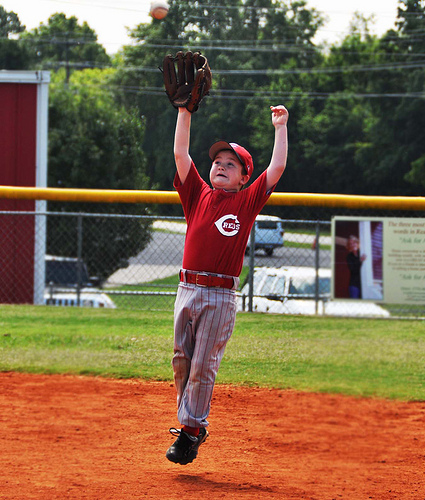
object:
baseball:
[150, 4, 168, 22]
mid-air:
[0, 1, 422, 63]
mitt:
[162, 48, 217, 115]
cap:
[208, 137, 254, 177]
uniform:
[173, 156, 277, 277]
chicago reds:
[213, 212, 241, 237]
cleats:
[165, 422, 209, 467]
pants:
[171, 267, 237, 434]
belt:
[174, 269, 237, 287]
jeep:
[244, 210, 287, 257]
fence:
[0, 210, 425, 321]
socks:
[180, 424, 203, 436]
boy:
[163, 49, 288, 466]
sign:
[330, 215, 423, 306]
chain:
[251, 220, 330, 307]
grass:
[0, 303, 425, 401]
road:
[126, 227, 339, 267]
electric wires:
[0, 0, 425, 107]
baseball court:
[0, 309, 425, 499]